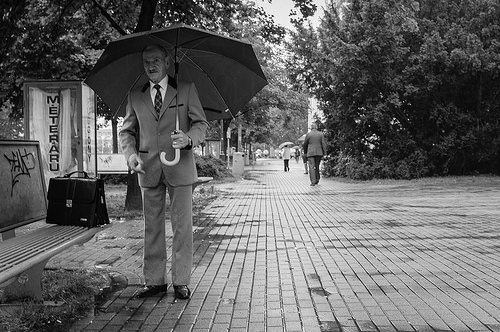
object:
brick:
[206, 245, 218, 256]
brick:
[320, 320, 338, 331]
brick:
[222, 233, 232, 239]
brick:
[102, 254, 120, 263]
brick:
[194, 229, 210, 244]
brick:
[178, 313, 200, 324]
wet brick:
[309, 284, 327, 303]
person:
[119, 44, 207, 296]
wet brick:
[250, 289, 269, 301]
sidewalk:
[5, 156, 500, 331]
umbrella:
[82, 22, 270, 166]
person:
[279, 140, 297, 174]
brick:
[266, 315, 287, 329]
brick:
[265, 300, 283, 311]